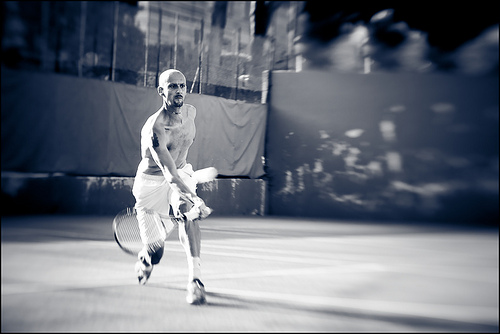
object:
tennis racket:
[112, 208, 214, 255]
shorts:
[132, 163, 197, 245]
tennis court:
[0, 214, 498, 333]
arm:
[143, 121, 211, 219]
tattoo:
[151, 132, 159, 150]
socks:
[187, 257, 201, 282]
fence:
[2, 1, 273, 102]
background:
[6, 71, 269, 119]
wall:
[258, 70, 493, 225]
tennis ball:
[194, 167, 218, 184]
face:
[163, 71, 188, 108]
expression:
[165, 76, 187, 107]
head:
[157, 69, 187, 107]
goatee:
[173, 95, 184, 107]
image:
[3, 2, 497, 326]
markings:
[320, 124, 438, 200]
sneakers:
[134, 261, 153, 285]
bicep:
[163, 146, 178, 173]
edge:
[108, 221, 133, 257]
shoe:
[186, 278, 207, 304]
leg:
[170, 188, 202, 278]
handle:
[190, 207, 212, 221]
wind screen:
[1, 66, 265, 180]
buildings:
[133, 1, 318, 70]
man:
[131, 69, 212, 306]